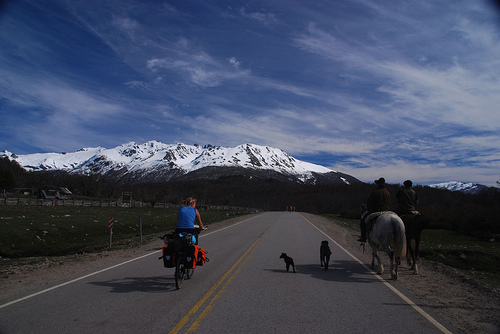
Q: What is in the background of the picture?
A: Snowy mountains.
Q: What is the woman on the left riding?
A: A bicycle.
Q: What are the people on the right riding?
A: Horses.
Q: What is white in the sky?
A: Clouds.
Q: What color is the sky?
A: Blue.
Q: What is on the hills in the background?
A: Snow.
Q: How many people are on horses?
A: Two.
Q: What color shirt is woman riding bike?
A: Blue.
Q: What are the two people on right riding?
A: Horses.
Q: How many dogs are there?
A: Two.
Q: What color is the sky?
A: Blue.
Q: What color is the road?
A: Gray.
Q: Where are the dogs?
A: In the street.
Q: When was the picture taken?
A: Daytime.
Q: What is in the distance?
A: Mountains.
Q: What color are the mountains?
A: White.